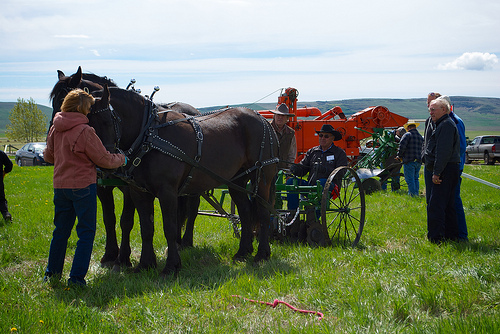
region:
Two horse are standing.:
[56, 50, 318, 297]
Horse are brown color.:
[105, 80, 249, 219]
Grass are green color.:
[326, 256, 442, 332]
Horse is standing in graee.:
[68, 78, 315, 320]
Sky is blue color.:
[1, 27, 106, 70]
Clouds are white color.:
[275, 11, 471, 41]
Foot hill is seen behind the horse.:
[0, 88, 466, 147]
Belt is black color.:
[121, 98, 218, 201]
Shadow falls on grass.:
[8, 206, 495, 324]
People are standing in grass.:
[4, 93, 484, 313]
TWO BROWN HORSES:
[0, 34, 289, 264]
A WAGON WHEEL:
[314, 165, 372, 255]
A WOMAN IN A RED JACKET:
[31, 92, 116, 198]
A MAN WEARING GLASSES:
[426, 96, 457, 121]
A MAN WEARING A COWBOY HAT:
[406, 111, 423, 141]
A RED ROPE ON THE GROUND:
[234, 275, 352, 332]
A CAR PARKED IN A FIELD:
[13, 128, 55, 165]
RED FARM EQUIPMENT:
[208, 100, 405, 167]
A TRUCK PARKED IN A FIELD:
[460, 130, 495, 184]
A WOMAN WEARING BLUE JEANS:
[26, 85, 98, 302]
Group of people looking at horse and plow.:
[419, 88, 482, 253]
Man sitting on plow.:
[300, 117, 357, 217]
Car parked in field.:
[15, 132, 52, 174]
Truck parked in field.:
[467, 120, 497, 174]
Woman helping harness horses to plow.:
[36, 93, 118, 298]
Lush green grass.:
[347, 257, 474, 325]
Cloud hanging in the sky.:
[433, 40, 498, 83]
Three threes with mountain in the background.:
[6, 92, 46, 146]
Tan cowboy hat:
[267, 100, 302, 120]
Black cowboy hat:
[314, 118, 346, 139]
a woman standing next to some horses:
[40, 94, 121, 276]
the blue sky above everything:
[1, 4, 488, 103]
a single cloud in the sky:
[453, 50, 497, 72]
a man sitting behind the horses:
[289, 126, 348, 218]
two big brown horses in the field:
[53, 68, 278, 279]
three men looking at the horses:
[418, 85, 467, 240]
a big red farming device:
[259, 90, 406, 163]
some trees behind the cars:
[8, 96, 44, 143]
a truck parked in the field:
[466, 130, 497, 162]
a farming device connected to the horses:
[268, 161, 363, 245]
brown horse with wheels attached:
[41, 45, 496, 283]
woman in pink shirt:
[41, 85, 136, 287]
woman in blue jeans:
[47, 91, 97, 282]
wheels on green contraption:
[237, 144, 418, 246]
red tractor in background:
[257, 68, 418, 168]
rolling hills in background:
[8, 74, 495, 146]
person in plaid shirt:
[401, 112, 425, 200]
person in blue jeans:
[390, 110, 428, 201]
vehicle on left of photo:
[2, 112, 64, 204]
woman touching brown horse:
[58, 62, 178, 274]